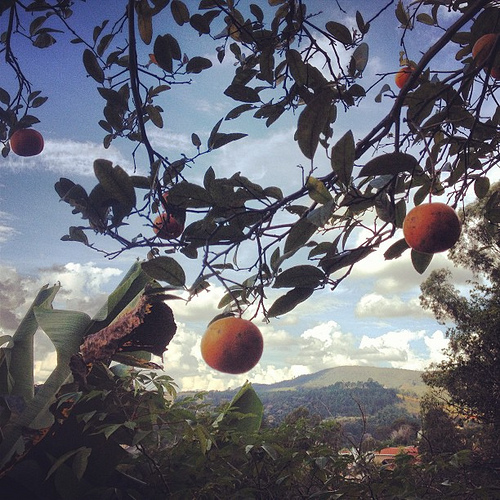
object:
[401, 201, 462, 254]
orange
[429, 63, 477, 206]
branch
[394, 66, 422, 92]
orange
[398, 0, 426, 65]
branch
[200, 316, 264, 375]
orange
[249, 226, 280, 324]
branch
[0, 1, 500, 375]
tree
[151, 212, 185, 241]
oranges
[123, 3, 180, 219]
branch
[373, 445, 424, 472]
house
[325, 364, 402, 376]
top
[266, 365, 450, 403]
mountain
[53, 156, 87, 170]
clouds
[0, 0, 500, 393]
sky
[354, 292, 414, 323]
clouds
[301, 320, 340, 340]
clouds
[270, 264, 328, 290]
leaf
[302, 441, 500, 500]
town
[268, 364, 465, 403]
area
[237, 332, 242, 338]
spots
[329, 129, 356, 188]
leaves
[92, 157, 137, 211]
leaves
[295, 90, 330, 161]
leaves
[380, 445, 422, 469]
roof